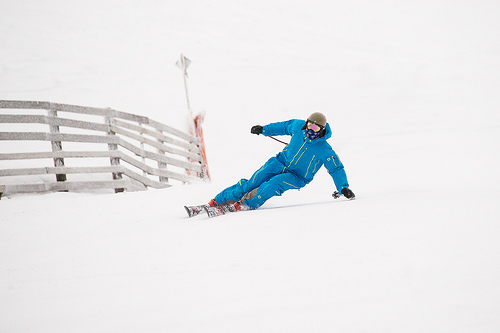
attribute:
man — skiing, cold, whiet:
[247, 92, 368, 213]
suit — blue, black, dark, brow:
[251, 124, 323, 201]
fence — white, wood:
[55, 102, 147, 191]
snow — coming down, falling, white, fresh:
[122, 211, 201, 255]